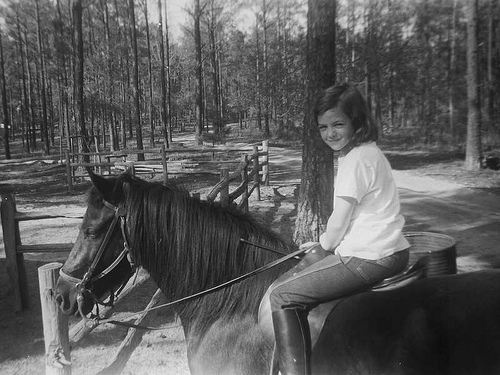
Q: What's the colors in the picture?
A: Black and white.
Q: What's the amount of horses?
A: One.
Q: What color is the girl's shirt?
A: White.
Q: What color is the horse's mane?
A: Black.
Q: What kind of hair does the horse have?
A: Straight.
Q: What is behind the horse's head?
A: A forest.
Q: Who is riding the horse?
A: A little girl.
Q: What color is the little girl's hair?
A: Black.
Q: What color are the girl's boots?
A: Black.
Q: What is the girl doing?
A: Riding a horse.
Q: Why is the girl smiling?
A: She is happy.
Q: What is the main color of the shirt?
A: White.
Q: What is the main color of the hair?
A: Brown.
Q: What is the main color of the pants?
A: Gray.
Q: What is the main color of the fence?
A: Brown.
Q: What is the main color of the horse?
A: Black.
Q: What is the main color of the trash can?
A: Gray.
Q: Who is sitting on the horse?
A: A girl.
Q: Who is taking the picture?
A: A photographer.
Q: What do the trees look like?
A: The trees are bare.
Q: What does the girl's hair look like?
A: The girl's hair is brown?.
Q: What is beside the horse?
A: A barrel.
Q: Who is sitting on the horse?
A: Girl.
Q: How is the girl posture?
A: Straight up.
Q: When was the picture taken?
A: Daytime.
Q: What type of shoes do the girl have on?
A: Boots.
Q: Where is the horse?
A: Ranch.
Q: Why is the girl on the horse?
A: To ride.